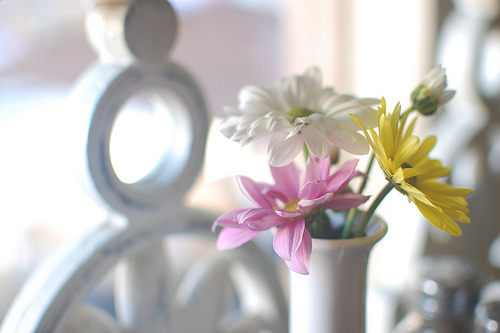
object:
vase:
[270, 207, 391, 333]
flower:
[352, 98, 472, 239]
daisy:
[208, 153, 372, 275]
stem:
[356, 180, 396, 238]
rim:
[271, 204, 388, 252]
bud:
[218, 67, 381, 165]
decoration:
[2, 1, 291, 332]